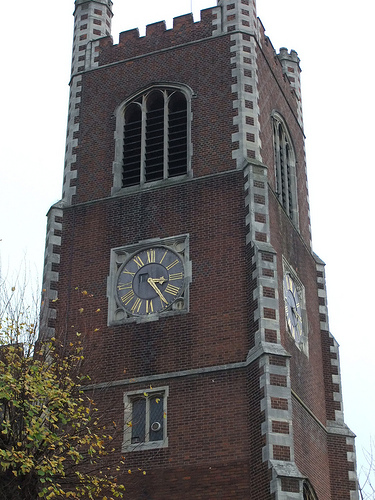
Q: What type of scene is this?
A: Outdoor.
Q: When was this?
A: Daytime.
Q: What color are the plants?
A: Green.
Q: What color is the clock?
A: Black.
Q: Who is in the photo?
A: No one.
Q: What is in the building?
A: Clock.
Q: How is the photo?
A: Clear.